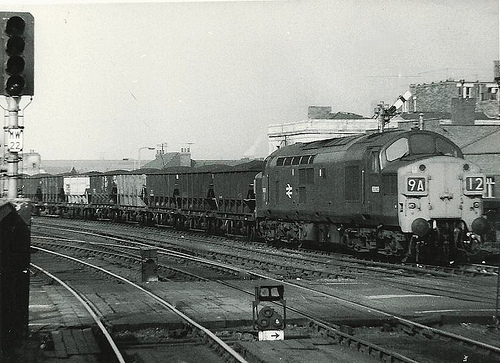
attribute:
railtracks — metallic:
[47, 243, 221, 353]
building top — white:
[259, 117, 386, 136]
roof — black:
[150, 149, 177, 168]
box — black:
[129, 244, 186, 294]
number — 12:
[466, 166, 495, 208]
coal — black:
[104, 164, 266, 171]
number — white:
[458, 174, 486, 197]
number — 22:
[11, 135, 23, 156]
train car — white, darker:
[60, 171, 90, 213]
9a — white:
[406, 178, 425, 192]